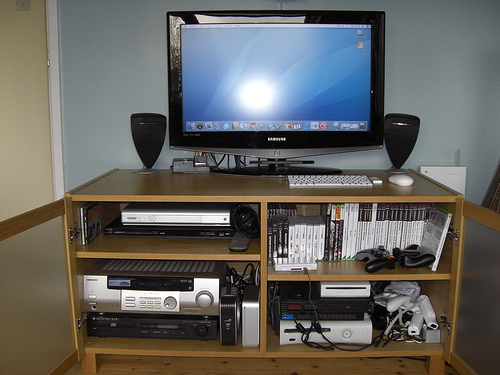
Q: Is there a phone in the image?
A: No, there are no phones.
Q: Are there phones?
A: No, there are no phones.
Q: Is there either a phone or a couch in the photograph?
A: No, there are no phones or couches.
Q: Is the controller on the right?
A: Yes, the controller is on the right of the image.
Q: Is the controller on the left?
A: No, the controller is on the right of the image.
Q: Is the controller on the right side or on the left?
A: The controller is on the right of the image.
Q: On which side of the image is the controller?
A: The controller is on the right of the image.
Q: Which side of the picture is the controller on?
A: The controller is on the right of the image.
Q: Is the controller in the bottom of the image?
A: Yes, the controller is in the bottom of the image.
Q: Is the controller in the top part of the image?
A: No, the controller is in the bottom of the image.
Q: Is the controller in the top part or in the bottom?
A: The controller is in the bottom of the image.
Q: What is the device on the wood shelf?
A: The device is a controller.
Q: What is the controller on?
A: The controller is on the shelf.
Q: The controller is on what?
A: The controller is on the shelf.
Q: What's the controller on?
A: The controller is on the shelf.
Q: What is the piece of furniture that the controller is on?
A: The piece of furniture is a shelf.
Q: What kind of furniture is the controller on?
A: The controller is on the shelf.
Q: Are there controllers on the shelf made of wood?
A: Yes, there is a controller on the shelf.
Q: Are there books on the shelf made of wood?
A: No, there is a controller on the shelf.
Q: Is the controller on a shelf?
A: Yes, the controller is on a shelf.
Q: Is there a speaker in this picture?
A: Yes, there is a speaker.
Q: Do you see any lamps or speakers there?
A: Yes, there is a speaker.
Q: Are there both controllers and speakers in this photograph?
A: Yes, there are both a speaker and a controller.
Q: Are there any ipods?
A: No, there are no ipods.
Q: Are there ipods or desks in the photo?
A: No, there are no ipods or desks.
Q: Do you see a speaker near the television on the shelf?
A: Yes, there is a speaker near the TV.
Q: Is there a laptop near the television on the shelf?
A: No, there is a speaker near the TV.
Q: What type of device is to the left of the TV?
A: The device is a speaker.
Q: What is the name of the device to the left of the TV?
A: The device is a speaker.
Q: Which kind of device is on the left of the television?
A: The device is a speaker.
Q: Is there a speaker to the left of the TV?
A: Yes, there is a speaker to the left of the TV.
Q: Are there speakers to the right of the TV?
A: No, the speaker is to the left of the TV.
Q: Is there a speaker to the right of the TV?
A: No, the speaker is to the left of the TV.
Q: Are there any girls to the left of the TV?
A: No, there is a speaker to the left of the TV.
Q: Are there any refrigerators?
A: No, there are no refrigerators.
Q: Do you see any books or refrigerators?
A: No, there are no refrigerators or books.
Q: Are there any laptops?
A: No, there are no laptops.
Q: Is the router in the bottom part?
A: Yes, the router is in the bottom of the image.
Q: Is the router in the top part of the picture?
A: No, the router is in the bottom of the image.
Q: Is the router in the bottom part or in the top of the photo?
A: The router is in the bottom of the image.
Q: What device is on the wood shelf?
A: The device is a router.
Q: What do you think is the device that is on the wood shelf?
A: The device is a router.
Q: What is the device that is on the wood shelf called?
A: The device is a router.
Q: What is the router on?
A: The router is on the shelf.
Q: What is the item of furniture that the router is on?
A: The piece of furniture is a shelf.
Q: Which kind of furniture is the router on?
A: The router is on the shelf.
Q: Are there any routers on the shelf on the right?
A: Yes, there is a router on the shelf.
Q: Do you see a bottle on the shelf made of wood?
A: No, there is a router on the shelf.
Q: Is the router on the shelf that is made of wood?
A: Yes, the router is on the shelf.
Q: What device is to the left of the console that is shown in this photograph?
A: The device is a router.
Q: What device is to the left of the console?
A: The device is a router.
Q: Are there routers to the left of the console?
A: Yes, there is a router to the left of the console.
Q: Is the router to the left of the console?
A: Yes, the router is to the left of the console.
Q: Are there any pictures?
A: No, there are no pictures.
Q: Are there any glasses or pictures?
A: No, there are no pictures or glasses.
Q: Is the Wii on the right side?
A: Yes, the Wii is on the right of the image.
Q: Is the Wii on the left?
A: No, the Wii is on the right of the image.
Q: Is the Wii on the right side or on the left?
A: The Wii is on the right of the image.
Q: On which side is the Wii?
A: The Wii is on the right of the image.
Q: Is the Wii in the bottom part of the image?
A: Yes, the Wii is in the bottom of the image.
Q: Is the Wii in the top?
A: No, the Wii is in the bottom of the image.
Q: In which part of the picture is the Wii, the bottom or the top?
A: The Wii is in the bottom of the image.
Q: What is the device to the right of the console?
A: The device is a Wii.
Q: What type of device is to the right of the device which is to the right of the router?
A: The device is a Wii.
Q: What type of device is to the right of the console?
A: The device is a Wii.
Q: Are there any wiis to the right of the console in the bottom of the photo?
A: Yes, there is a Wii to the right of the console.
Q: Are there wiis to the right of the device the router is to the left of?
A: Yes, there is a Wii to the right of the console.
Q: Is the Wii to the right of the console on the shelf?
A: Yes, the Wii is to the right of the console.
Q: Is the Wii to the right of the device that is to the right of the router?
A: Yes, the Wii is to the right of the console.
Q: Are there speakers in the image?
A: Yes, there are speakers.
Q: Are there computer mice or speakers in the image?
A: Yes, there are speakers.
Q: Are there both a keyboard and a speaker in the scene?
A: Yes, there are both a speaker and a keyboard.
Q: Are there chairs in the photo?
A: No, there are no chairs.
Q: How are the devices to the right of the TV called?
A: The devices are speakers.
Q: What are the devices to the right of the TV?
A: The devices are speakers.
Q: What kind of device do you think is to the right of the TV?
A: The devices are speakers.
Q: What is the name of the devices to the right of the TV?
A: The devices are speakers.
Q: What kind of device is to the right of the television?
A: The devices are speakers.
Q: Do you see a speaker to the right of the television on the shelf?
A: Yes, there are speakers to the right of the television.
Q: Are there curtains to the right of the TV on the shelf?
A: No, there are speakers to the right of the TV.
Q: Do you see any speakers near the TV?
A: Yes, there are speakers near the TV.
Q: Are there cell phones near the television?
A: No, there are speakers near the television.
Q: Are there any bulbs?
A: No, there are no bulbs.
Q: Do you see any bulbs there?
A: No, there are no bulbs.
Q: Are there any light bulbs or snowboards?
A: No, there are no light bulbs or snowboards.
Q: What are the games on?
A: The games are on the shelf.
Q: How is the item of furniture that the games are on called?
A: The piece of furniture is a shelf.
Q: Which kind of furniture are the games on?
A: The games are on the shelf.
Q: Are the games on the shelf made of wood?
A: Yes, the games are on the shelf.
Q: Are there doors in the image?
A: Yes, there are doors.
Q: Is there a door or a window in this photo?
A: Yes, there are doors.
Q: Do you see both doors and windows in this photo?
A: No, there are doors but no windows.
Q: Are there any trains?
A: No, there are no trains.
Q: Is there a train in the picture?
A: No, there are no trains.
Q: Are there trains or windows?
A: No, there are no trains or windows.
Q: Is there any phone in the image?
A: No, there are no phones.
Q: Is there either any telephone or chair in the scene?
A: No, there are no phones or chairs.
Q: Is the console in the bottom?
A: Yes, the console is in the bottom of the image.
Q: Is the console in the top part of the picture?
A: No, the console is in the bottom of the image.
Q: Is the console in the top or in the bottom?
A: The console is in the bottom of the image.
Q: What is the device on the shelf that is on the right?
A: The device is a console.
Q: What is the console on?
A: The console is on the shelf.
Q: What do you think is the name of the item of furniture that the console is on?
A: The piece of furniture is a shelf.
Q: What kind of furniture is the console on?
A: The console is on the shelf.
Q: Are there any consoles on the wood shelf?
A: Yes, there is a console on the shelf.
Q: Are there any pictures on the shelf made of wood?
A: No, there is a console on the shelf.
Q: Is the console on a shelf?
A: Yes, the console is on a shelf.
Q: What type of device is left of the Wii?
A: The device is a console.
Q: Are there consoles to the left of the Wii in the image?
A: Yes, there is a console to the left of the Wii.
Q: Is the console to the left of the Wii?
A: Yes, the console is to the left of the Wii.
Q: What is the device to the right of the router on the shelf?
A: The device is a console.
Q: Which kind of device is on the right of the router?
A: The device is a console.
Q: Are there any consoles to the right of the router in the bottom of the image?
A: Yes, there is a console to the right of the router.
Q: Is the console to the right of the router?
A: Yes, the console is to the right of the router.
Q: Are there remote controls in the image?
A: Yes, there is a remote control.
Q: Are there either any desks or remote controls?
A: Yes, there is a remote control.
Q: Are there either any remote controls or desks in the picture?
A: Yes, there is a remote control.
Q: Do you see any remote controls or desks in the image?
A: Yes, there is a remote control.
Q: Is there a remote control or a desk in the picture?
A: Yes, there is a remote control.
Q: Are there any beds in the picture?
A: No, there are no beds.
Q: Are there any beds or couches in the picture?
A: No, there are no beds or couches.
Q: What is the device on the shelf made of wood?
A: The device is a remote control.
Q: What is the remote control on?
A: The remote control is on the shelf.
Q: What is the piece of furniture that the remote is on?
A: The piece of furniture is a shelf.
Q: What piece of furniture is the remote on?
A: The remote is on the shelf.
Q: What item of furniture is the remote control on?
A: The remote is on the shelf.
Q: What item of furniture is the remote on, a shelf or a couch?
A: The remote is on a shelf.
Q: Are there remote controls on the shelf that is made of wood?
A: Yes, there is a remote control on the shelf.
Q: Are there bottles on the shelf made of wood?
A: No, there is a remote control on the shelf.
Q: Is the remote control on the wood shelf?
A: Yes, the remote control is on the shelf.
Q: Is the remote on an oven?
A: No, the remote is on the shelf.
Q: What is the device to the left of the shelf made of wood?
A: The device is a remote control.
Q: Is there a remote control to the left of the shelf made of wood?
A: Yes, there is a remote control to the left of the shelf.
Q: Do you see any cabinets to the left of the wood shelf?
A: No, there is a remote control to the left of the shelf.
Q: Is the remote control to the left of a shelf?
A: Yes, the remote control is to the left of a shelf.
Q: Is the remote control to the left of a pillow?
A: No, the remote control is to the left of a shelf.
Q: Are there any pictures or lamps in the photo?
A: No, there are no pictures or lamps.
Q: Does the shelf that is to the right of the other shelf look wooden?
A: Yes, the shelf is wooden.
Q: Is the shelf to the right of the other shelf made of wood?
A: Yes, the shelf is made of wood.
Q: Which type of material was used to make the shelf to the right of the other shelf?
A: The shelf is made of wood.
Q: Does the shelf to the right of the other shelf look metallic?
A: No, the shelf is wooden.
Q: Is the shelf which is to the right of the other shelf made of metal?
A: No, the shelf is made of wood.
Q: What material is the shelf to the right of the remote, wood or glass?
A: The shelf is made of wood.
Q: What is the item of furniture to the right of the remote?
A: The piece of furniture is a shelf.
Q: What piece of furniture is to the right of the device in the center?
A: The piece of furniture is a shelf.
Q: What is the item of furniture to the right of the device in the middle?
A: The piece of furniture is a shelf.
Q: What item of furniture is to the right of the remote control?
A: The piece of furniture is a shelf.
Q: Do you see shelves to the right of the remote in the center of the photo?
A: Yes, there is a shelf to the right of the remote.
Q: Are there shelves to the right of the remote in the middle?
A: Yes, there is a shelf to the right of the remote.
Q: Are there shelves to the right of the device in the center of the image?
A: Yes, there is a shelf to the right of the remote.